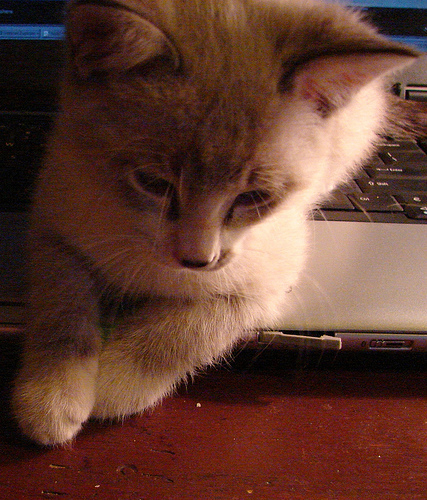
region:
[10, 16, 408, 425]
kitten sitting on laptop keyboard.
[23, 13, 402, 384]
adorable kitten sitting on laptop keyboard.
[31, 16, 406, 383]
cute kitten sitting on laptop keyboard.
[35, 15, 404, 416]
loveable kitten sitting on laptop keyboard.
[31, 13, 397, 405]
pretty kitten sitting on laptop keyboard.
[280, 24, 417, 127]
left ear of a kitten.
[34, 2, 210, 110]
right ear of a kitten.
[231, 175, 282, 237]
left eye of a precious kitten.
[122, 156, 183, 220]
right eye of a kitten.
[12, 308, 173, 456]
cute paws of a kitten.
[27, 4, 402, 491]
a cat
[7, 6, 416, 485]
a kitten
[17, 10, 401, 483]
a kitten is lying on a keyboard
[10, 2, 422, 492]
a kitten plays on a laptop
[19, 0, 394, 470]
the kitten is tan and white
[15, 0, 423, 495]
the laptop is turned on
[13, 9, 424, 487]
the laptop is on a red surface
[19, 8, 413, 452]
the kitten looks down at a red table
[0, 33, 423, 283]
the keyboard is black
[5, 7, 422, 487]
a kitten with long fur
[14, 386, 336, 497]
desk is wooden and scratched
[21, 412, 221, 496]
desk is wooden and scratched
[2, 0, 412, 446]
a tired kitten lying down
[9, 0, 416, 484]
the kitten is lying on a laptop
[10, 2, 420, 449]
the kitten has fuzzy fur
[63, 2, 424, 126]
the ears of the kitten are black rimmed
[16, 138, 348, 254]
the kitty has whiskers above his eyes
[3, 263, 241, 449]
the paws are crossed in front of the cat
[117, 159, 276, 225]
the kitty has dark eyes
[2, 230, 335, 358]
the kitty has long whiskers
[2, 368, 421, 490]
a brown wooden desk is under the paws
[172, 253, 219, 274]
the tip of the cat's nose is black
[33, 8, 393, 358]
C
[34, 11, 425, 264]
A cat on a keyboard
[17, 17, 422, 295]
A cat on a laptop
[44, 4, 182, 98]
The right ear of a cat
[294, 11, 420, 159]
The left ear of a cat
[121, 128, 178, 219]
The right eye of a cat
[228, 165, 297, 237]
The left eye of a cat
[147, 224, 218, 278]
The nose of a cat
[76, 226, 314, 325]
The whiskers of a cat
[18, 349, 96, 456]
The paw of a cat